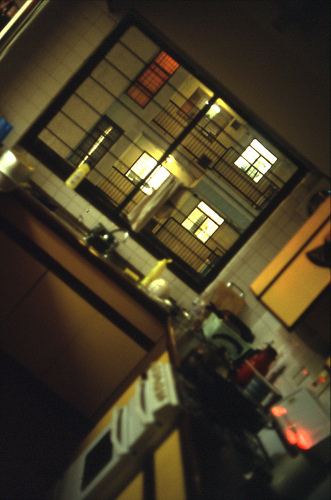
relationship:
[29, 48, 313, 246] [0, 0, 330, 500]
window in building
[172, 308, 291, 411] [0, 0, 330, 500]
pot in building